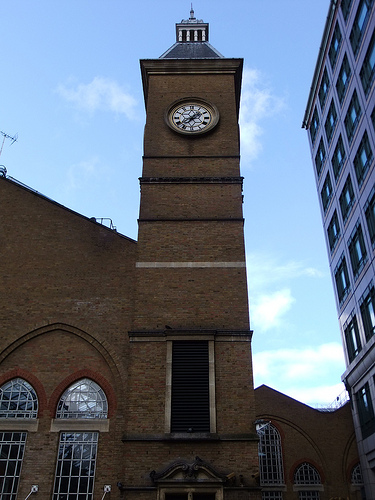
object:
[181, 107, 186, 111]
roman numeral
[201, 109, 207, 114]
roman numeral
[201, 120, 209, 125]
roman numeral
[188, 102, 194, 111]
numeral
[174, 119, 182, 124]
numeral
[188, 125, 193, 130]
roman numeral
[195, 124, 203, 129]
roman numeral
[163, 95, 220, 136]
clock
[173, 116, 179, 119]
roman numeral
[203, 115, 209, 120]
numeral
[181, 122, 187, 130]
numeral